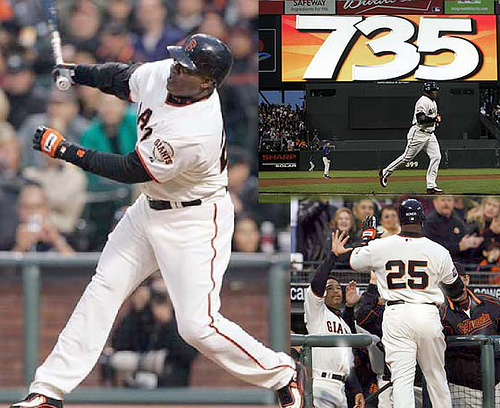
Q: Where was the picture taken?
A: In a stadium.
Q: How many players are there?
A: 1.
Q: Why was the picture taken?
A: To show the player.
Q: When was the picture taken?
A: During a game.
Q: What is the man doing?
A: Hitting ball, greeting players and running.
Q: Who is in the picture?
A: Giants player.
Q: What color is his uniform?
A: White.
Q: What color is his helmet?
A: Blue.